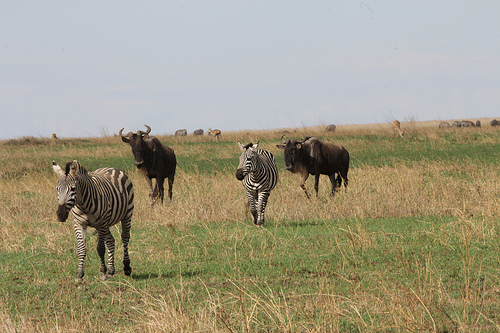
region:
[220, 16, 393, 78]
this is the sky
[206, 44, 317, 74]
the sky is blue in color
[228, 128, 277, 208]
this is a zebra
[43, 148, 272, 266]
the zebras are two in number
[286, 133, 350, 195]
this is a buffalo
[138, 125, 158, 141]
this is the horn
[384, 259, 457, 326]
this is a grass area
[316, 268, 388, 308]
the grass is green in color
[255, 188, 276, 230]
this is the leg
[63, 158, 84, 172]
this is the ear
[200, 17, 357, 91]
this is the sky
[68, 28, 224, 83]
the sky is blue in color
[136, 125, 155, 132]
this is a horn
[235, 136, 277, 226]
this is a zebra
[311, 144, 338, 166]
the buffalo is brown in color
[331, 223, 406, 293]
this is a grass area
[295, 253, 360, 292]
the grass is green in color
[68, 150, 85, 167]
this is a ear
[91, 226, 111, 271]
this is the leg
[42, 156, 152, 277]
zebra on grassy field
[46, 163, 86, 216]
head of a zebra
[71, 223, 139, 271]
legs of a zebra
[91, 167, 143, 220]
body of zebra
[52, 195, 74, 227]
mouth of zebra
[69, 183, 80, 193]
eyes of zebra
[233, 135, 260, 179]
head of a zebra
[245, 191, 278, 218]
legs of a zebra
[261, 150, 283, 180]
body of a zebra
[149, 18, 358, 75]
clear blue skies with no cloud and fog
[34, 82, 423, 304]
animals on a terrain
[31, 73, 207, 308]
zebra being chased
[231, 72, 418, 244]
zebra being chased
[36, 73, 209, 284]
gnu chasing a zebra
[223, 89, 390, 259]
gnu chasing a zebra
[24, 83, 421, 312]
two zebras being chased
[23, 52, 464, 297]
two zebras being chased by gnus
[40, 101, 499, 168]
animals grazing in the sun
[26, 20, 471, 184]
animals grazing in grass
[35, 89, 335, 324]
zebras running for their lives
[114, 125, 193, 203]
animal in the grass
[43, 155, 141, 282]
animal in the grass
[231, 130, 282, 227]
animal in the grass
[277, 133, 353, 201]
animal in the grass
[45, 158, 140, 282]
zebra in the grass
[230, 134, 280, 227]
zebra in the grass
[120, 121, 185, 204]
wilderbeast in the grass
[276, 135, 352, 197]
wilderbeast in the grass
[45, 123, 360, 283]
animals walking in the grass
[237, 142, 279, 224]
black and white animal in the grass